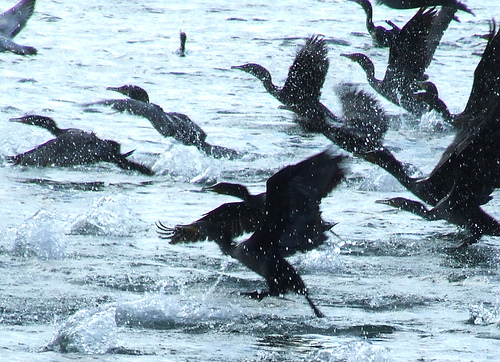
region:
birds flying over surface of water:
[36, 80, 461, 311]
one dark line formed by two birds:
[226, 46, 436, 197]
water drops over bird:
[10, 87, 150, 202]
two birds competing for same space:
[161, 140, 353, 315]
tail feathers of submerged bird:
[165, 20, 200, 65]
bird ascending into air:
[90, 65, 237, 170]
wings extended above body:
[340, 2, 455, 134]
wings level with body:
[6, 110, 156, 200]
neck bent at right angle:
[370, 175, 470, 225]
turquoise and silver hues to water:
[67, 25, 335, 180]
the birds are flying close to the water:
[21, 73, 494, 290]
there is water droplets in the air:
[80, 193, 160, 293]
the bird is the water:
[156, 25, 226, 74]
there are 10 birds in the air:
[9, 7, 496, 265]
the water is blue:
[104, 285, 199, 331]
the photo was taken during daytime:
[4, 8, 496, 360]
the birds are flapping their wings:
[38, 93, 470, 282]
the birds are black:
[146, 113, 392, 295]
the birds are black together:
[81, 85, 496, 294]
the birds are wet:
[5, 51, 482, 263]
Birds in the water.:
[45, 32, 390, 311]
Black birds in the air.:
[135, 145, 379, 320]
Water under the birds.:
[113, 15, 360, 217]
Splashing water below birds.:
[70, 119, 359, 264]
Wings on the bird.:
[16, 114, 128, 176]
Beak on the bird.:
[212, 56, 267, 84]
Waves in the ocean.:
[55, 285, 206, 357]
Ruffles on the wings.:
[144, 225, 206, 252]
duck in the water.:
[152, 23, 198, 62]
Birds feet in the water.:
[229, 272, 308, 317]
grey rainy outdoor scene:
[7, 0, 497, 347]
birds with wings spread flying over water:
[3, 1, 495, 319]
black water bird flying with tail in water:
[146, 139, 356, 322]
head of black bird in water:
[173, 25, 193, 61]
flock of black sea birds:
[8, 0, 495, 329]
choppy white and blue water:
[7, 0, 496, 350]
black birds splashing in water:
[4, 0, 499, 343]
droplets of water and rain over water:
[6, 0, 488, 352]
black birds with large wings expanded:
[2, 0, 499, 311]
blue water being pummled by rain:
[5, 1, 495, 354]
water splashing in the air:
[175, 276, 226, 320]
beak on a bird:
[371, 191, 386, 211]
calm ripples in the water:
[106, 17, 144, 70]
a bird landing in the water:
[163, 149, 337, 240]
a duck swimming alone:
[164, 24, 207, 55]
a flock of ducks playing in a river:
[26, 6, 495, 322]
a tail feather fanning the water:
[299, 292, 331, 332]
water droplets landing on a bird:
[413, 204, 430, 220]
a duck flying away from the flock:
[4, 0, 58, 75]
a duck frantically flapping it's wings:
[305, 94, 405, 177]